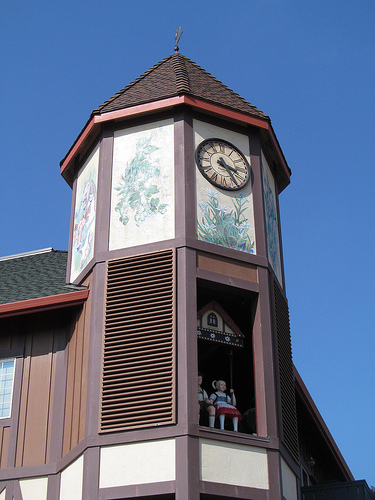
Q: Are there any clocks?
A: Yes, there is a clock.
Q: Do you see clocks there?
A: Yes, there is a clock.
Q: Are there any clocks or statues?
A: Yes, there is a clock.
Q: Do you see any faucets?
A: No, there are no faucets.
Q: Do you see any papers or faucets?
A: No, there are no faucets or papers.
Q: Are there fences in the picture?
A: No, there are no fences.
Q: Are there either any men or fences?
A: No, there are no fences or men.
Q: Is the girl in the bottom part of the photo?
A: Yes, the girl is in the bottom of the image.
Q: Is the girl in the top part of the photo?
A: No, the girl is in the bottom of the image.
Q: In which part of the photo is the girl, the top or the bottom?
A: The girl is in the bottom of the image.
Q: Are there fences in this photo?
A: No, there are no fences.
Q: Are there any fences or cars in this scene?
A: No, there are no fences or cars.